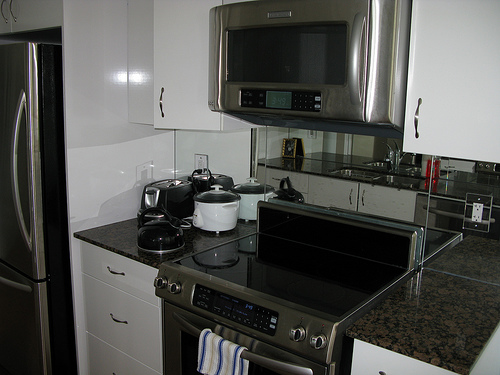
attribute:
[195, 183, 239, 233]
crock pot — small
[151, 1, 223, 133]
cabinets — white 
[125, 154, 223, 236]
oven — black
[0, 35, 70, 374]
refrigerator — huge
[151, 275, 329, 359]
knobs — chrome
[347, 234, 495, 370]
countertop — patterned, marble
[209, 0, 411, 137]
microwave — above, silver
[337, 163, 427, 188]
sink — double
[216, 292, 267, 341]
clock — small, illuminated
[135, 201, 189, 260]
tea kettle — black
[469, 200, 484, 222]
outlet — white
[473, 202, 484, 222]
outlet — electrical, mounted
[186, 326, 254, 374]
dishtowel — hanging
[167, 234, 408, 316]
stove top — electric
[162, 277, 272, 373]
towel — white, blue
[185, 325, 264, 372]
towel — blue, beige, striped, hanging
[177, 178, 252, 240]
crock pot — white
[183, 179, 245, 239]
cooker — white 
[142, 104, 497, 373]
wall — mirrored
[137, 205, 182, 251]
teapot — black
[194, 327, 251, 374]
towel — hanging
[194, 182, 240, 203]
lid — glass